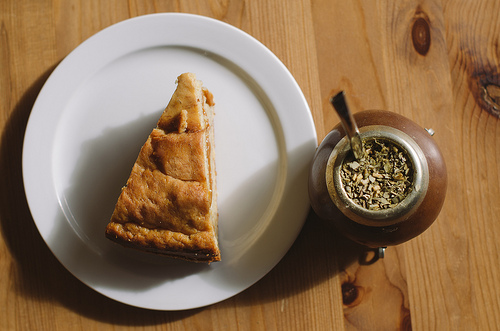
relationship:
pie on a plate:
[83, 59, 224, 265] [22, 12, 320, 291]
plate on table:
[22, 12, 320, 291] [12, 6, 500, 328]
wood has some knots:
[318, 0, 499, 105] [467, 71, 498, 118]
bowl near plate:
[306, 109, 448, 256] [22, 12, 320, 291]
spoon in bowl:
[330, 88, 378, 168] [306, 109, 448, 256]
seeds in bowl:
[364, 159, 396, 190] [306, 109, 448, 256]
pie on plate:
[83, 59, 224, 265] [22, 12, 320, 291]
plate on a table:
[22, 12, 320, 291] [12, 6, 500, 328]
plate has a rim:
[22, 12, 320, 312] [123, 19, 141, 32]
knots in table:
[467, 71, 498, 118] [12, 6, 500, 328]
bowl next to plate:
[306, 109, 448, 256] [22, 12, 320, 291]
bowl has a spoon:
[306, 109, 448, 256] [330, 88, 378, 168]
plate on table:
[22, 12, 320, 312] [12, 6, 500, 328]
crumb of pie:
[171, 111, 191, 134] [83, 59, 224, 265]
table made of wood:
[12, 6, 500, 328] [318, 0, 499, 105]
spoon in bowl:
[330, 88, 378, 168] [321, 126, 441, 225]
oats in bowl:
[371, 163, 403, 184] [321, 126, 441, 225]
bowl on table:
[321, 126, 441, 225] [12, 6, 500, 328]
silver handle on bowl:
[423, 123, 440, 140] [321, 126, 441, 225]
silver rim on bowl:
[410, 154, 429, 187] [321, 126, 441, 225]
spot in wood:
[405, 18, 434, 49] [318, 0, 499, 105]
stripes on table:
[253, 10, 316, 38] [12, 6, 500, 328]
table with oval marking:
[12, 6, 500, 328] [334, 276, 362, 304]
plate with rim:
[22, 12, 320, 312] [123, 19, 141, 32]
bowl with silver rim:
[306, 109, 448, 256] [410, 154, 429, 187]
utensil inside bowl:
[330, 88, 378, 168] [306, 109, 448, 256]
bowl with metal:
[306, 109, 448, 256] [376, 208, 394, 218]